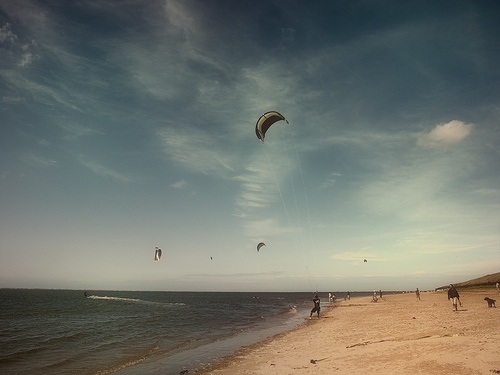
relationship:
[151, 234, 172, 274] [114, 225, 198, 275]
parasail in sky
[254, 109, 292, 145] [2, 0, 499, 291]
parasail in sky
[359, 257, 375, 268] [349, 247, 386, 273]
parasail in sky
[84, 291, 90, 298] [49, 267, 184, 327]
man parasailing in ocean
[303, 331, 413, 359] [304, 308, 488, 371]
sand on beach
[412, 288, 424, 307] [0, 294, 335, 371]
people are on beach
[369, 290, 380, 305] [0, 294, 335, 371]
people are on beach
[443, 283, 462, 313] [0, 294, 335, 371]
people are on beach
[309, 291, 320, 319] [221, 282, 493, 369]
man on beach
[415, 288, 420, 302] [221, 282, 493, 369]
people on beach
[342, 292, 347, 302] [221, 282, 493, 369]
person on beach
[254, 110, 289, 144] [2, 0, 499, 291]
kite in sky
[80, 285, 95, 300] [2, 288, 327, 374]
man in water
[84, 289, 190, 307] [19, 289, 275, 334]
waves are in water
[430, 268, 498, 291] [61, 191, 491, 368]
hill extending to beach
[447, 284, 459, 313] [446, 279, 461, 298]
people wearing jacket.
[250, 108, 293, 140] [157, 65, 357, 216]
kite flying in sky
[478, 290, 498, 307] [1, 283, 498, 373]
dog on beach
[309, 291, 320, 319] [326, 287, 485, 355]
man are on beach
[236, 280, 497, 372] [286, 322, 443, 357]
shore covered in sand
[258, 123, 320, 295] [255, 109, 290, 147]
string hanging from kite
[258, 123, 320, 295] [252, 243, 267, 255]
string hanging from kite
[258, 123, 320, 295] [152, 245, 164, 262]
string hanging from kite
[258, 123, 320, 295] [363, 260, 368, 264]
string hanging from kite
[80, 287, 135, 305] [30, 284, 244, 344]
wake in water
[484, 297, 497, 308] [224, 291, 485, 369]
dog walking on beach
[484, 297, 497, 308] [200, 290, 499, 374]
dog standing on sand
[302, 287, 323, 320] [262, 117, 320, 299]
man pulling strings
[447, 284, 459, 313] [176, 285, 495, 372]
people strolling along beach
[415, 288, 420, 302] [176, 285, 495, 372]
people strolling along beach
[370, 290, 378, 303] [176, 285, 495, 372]
people strolling along beach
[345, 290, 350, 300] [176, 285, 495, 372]
person strolling along beach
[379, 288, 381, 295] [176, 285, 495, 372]
person strolling along beach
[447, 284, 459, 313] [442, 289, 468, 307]
people wearing capris